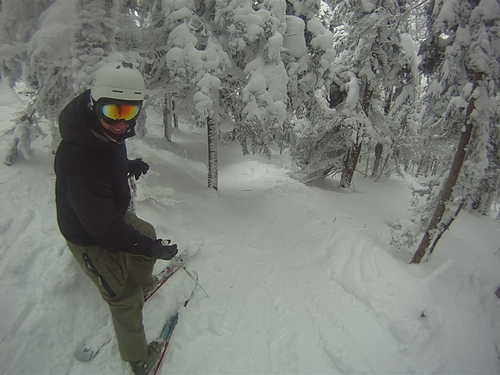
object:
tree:
[149, 0, 266, 186]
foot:
[143, 274, 159, 298]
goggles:
[94, 100, 143, 125]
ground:
[0, 159, 500, 374]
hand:
[154, 238, 179, 260]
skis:
[75, 237, 197, 375]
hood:
[94, 123, 136, 145]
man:
[51, 59, 177, 375]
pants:
[64, 214, 156, 363]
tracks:
[220, 201, 420, 373]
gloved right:
[152, 238, 180, 261]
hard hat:
[88, 66, 145, 139]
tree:
[409, 0, 498, 268]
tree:
[367, 30, 422, 184]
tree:
[149, 0, 188, 144]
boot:
[128, 336, 168, 374]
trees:
[0, 0, 146, 163]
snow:
[0, 0, 500, 375]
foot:
[130, 335, 164, 374]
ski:
[74, 243, 198, 375]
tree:
[286, 0, 424, 193]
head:
[85, 67, 148, 140]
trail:
[177, 125, 437, 246]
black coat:
[54, 88, 154, 255]